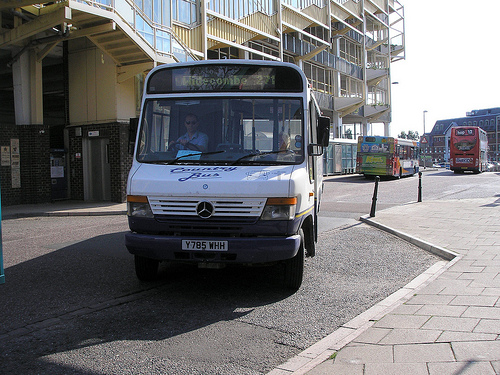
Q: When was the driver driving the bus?
A: During work hours.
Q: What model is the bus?
A: Mercedes.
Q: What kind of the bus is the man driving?
A: Courtesy.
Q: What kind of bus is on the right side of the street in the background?
A: Double decker.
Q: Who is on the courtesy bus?
A: A driver and passenger.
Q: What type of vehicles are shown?
A: Buses.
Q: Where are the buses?
A: Street.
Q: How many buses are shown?
A: Three.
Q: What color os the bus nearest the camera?
A: White.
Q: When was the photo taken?
A: Daytime.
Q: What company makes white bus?
A: Mercedes.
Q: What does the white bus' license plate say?
A: Y785 WHH.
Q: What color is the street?
A: Gray.